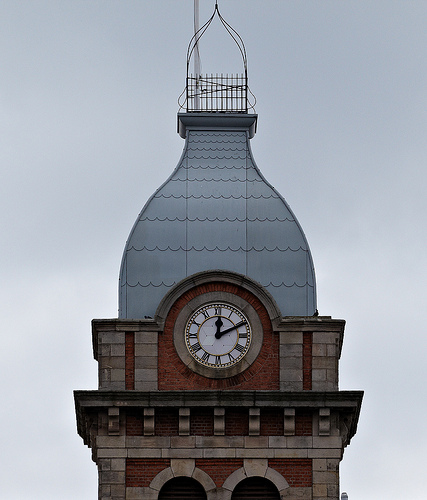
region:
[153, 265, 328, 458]
a clock is on the building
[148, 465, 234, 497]
the building has arches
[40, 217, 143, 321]
the sky is gray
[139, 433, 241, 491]
the building has rust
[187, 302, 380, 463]
the clock has black hands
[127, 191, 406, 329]
above the clock is gray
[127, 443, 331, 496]
two arches are present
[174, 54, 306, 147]
wire is on the roof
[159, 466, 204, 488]
the spaces are dark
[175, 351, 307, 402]
rust runs from the clock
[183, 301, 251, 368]
the clock on the tower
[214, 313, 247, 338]
the hands on the clock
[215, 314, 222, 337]
the hour hand on the clock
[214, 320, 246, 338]
the minutes hand on the clock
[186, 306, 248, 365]
the roman numerals on the clock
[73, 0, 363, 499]
the tall clock tower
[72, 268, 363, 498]
the bricks on the clock tower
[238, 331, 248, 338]
the roman numeral 3 on the clock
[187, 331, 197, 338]
the roman numeral 9 on the clock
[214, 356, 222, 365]
the roman numeral 6 on the clock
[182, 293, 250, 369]
black and white clock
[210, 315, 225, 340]
black clock hour hand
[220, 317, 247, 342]
black clock minute hand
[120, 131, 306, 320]
waved grooves on ceiling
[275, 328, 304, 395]
dirty white stone line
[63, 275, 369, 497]
tall brick clock tower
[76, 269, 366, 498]
stone and brick building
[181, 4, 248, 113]
black metal gate on top of tower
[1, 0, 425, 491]
cloudy sky in the color of white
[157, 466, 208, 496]
dark black arc in building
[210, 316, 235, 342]
hands on the clock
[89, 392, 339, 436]
pillars of the tower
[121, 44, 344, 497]
this is a clock tower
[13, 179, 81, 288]
the sky is grey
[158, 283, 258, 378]
clock on the tower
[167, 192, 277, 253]
the roof is blue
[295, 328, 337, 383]
bricks on the tower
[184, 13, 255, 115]
top of the tower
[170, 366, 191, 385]
the building is red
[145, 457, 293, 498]
arches of the building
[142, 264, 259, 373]
clock on the water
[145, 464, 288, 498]
arches of the tower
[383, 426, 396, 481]
the sky is grey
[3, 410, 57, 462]
the sky is cloudy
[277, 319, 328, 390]
bricks on the tower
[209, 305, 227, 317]
numbers on the clock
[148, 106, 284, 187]
part of tower is blue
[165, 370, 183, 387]
part of tower is red